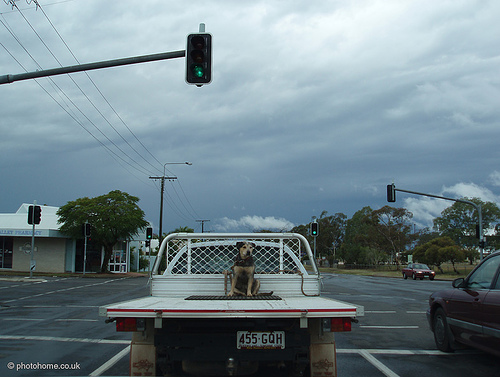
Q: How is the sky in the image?
A: It is dark and overcast.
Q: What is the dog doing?
A: Sitting down.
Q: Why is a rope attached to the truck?
A: It is attached to the dog's collar.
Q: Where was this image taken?
A: On a street.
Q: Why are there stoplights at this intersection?
A: To regulate traffic.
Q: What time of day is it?
A: Evening.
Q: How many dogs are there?
A: One.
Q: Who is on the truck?
A: A dog.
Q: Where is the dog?
A: The truck.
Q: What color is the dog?
A: Brown.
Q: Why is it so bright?
A: Sunlight.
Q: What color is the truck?
A: White.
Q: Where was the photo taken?
A: At a street intersection.